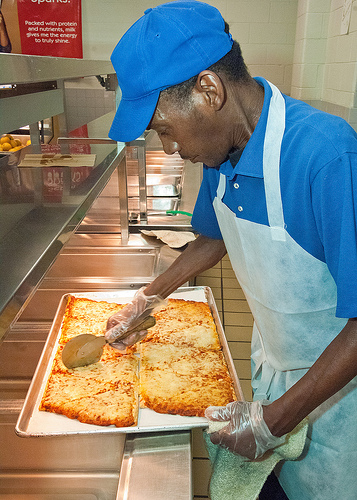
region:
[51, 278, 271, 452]
man holding pizza tray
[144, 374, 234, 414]
triangle slice of pizza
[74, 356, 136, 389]
triangle slice of pizza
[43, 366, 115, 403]
triangle slice of pizza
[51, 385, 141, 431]
triangle slice of pizza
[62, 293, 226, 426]
cheese pizza on tray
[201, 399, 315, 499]
hand towel used to hold tray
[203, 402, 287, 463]
man's disposable glove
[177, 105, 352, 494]
man wearing paper apron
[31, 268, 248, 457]
man cutting pizza into slices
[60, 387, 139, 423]
triangle slice in pizza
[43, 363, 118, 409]
triangle slice in pizza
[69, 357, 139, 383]
triangle slice in pizza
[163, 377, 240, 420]
triangle slice in pizza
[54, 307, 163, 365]
round blade pizza cutter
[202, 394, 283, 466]
man's transparent disposable glove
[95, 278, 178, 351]
man's transparent disposable glove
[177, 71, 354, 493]
man wearing a white apron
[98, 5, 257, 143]
man wearing a blue cap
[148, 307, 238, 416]
slices of cheese pizza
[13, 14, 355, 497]
fast-food worker cutting pizza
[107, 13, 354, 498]
black man wearing blue polo shirt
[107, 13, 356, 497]
worker wearing white apron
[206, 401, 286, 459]
transparent plastic glove on left hand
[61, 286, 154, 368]
right hand holding pizza cutter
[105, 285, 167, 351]
transparent plastic glove on right hand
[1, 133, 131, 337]
shiny stainless steel counter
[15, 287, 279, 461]
left hand holding plastic tray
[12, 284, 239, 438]
pizza on plastic tray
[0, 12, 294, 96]
red sign on white wall made of concrete blocks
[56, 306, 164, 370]
A wood handle pizza cutter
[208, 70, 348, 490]
A white chef gown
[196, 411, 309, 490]
A small dirty towel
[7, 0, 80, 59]
A red sign on the wall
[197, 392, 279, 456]
A clear plastic glove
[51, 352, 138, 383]
A piece of cheese pizza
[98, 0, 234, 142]
A blue baseball cap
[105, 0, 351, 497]
A man in a white shirt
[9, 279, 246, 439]
A silver tray of pizza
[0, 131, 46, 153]
A tub of oranges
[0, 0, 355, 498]
A cafeteria scene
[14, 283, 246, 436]
This is a baking sheet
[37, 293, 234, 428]
Pizza is on the baking sheet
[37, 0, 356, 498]
The man is cutting the pizza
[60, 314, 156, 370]
A pizza cutting wheel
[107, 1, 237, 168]
The man is wearing a blue hat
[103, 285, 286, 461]
The man has gloves on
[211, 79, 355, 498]
The man is wearing a white apron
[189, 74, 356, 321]
The man's shirt is blue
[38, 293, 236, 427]
The pizza has cheese on it